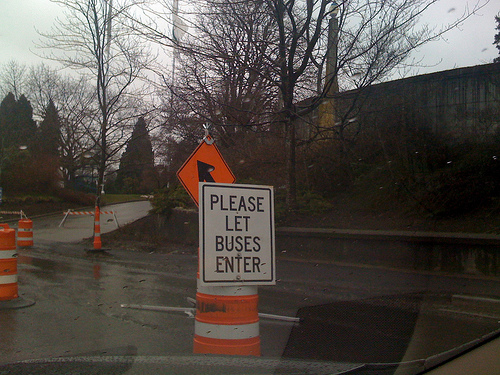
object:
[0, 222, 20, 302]
cones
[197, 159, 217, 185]
arrow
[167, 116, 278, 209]
traffic sign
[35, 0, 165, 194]
pine trees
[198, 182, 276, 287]
sign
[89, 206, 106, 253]
cone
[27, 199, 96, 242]
cement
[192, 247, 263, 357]
traffic barrel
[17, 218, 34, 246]
traffic barrel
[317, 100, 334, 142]
post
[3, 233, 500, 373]
street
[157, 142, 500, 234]
hill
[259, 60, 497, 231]
wall